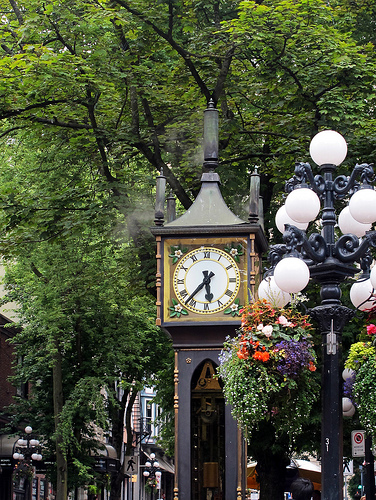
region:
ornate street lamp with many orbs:
[259, 118, 374, 384]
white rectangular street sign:
[350, 425, 367, 465]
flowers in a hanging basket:
[208, 296, 325, 442]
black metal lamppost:
[313, 312, 354, 495]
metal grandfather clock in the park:
[136, 159, 273, 497]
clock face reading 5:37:
[162, 239, 254, 321]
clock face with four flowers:
[161, 237, 248, 317]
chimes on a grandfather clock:
[180, 352, 234, 498]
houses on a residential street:
[2, 304, 166, 497]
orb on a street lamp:
[307, 128, 349, 164]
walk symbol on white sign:
[123, 453, 140, 473]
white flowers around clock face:
[166, 243, 191, 263]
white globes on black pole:
[285, 189, 321, 221]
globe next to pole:
[284, 188, 321, 222]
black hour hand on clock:
[202, 270, 213, 302]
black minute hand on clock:
[184, 272, 217, 304]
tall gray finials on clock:
[201, 97, 223, 170]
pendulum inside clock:
[201, 461, 221, 487]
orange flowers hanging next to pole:
[252, 350, 271, 361]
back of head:
[288, 476, 314, 498]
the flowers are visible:
[192, 304, 302, 435]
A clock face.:
[163, 237, 247, 319]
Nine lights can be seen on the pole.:
[228, 126, 374, 318]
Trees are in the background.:
[6, 55, 139, 319]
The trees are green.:
[6, 52, 140, 302]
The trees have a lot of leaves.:
[8, 52, 139, 299]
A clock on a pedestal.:
[137, 92, 273, 498]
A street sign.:
[338, 416, 374, 480]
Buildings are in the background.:
[0, 309, 168, 496]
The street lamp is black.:
[255, 115, 375, 494]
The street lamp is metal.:
[250, 124, 373, 493]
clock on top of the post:
[116, 211, 259, 379]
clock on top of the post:
[123, 174, 340, 343]